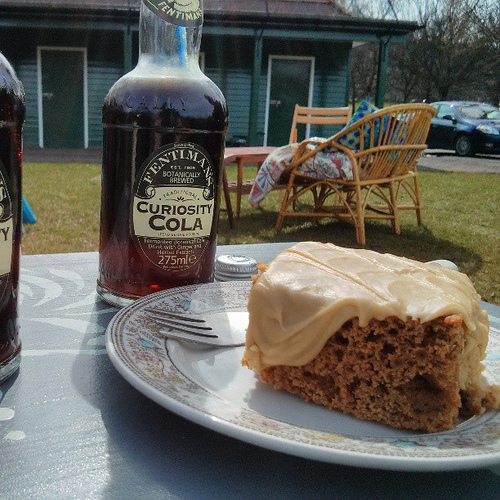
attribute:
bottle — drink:
[77, 3, 263, 301]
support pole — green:
[377, 42, 388, 109]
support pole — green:
[245, 34, 267, 146]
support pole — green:
[119, 27, 134, 77]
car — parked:
[402, 91, 498, 152]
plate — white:
[99, 278, 499, 477]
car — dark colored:
[428, 95, 498, 164]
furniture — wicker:
[273, 102, 435, 245]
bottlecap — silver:
[213, 254, 259, 282]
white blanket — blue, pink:
[228, 108, 405, 181]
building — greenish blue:
[0, 8, 422, 145]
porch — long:
[19, 146, 104, 166]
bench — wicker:
[275, 99, 437, 245]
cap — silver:
[214, 251, 259, 281]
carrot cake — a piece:
[241, 239, 498, 431]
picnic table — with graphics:
[221, 143, 306, 223]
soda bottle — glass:
[98, 16, 219, 307]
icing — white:
[243, 238, 484, 365]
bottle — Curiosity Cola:
[96, 3, 228, 306]